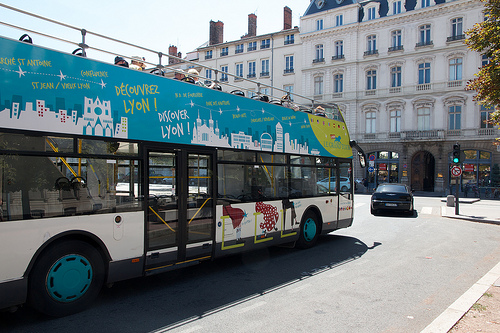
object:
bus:
[0, 4, 367, 322]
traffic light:
[451, 144, 460, 165]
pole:
[453, 172, 461, 214]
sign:
[449, 165, 464, 179]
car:
[371, 181, 417, 217]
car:
[316, 175, 354, 193]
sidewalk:
[440, 197, 500, 224]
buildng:
[146, 6, 298, 106]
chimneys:
[283, 5, 293, 31]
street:
[0, 190, 499, 332]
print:
[153, 108, 192, 141]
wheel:
[16, 233, 110, 318]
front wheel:
[294, 207, 325, 250]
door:
[143, 144, 187, 269]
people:
[127, 54, 147, 73]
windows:
[421, 29, 430, 46]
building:
[296, 0, 500, 201]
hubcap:
[44, 254, 94, 305]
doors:
[178, 148, 217, 264]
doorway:
[408, 147, 436, 196]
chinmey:
[245, 13, 258, 38]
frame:
[138, 139, 218, 158]